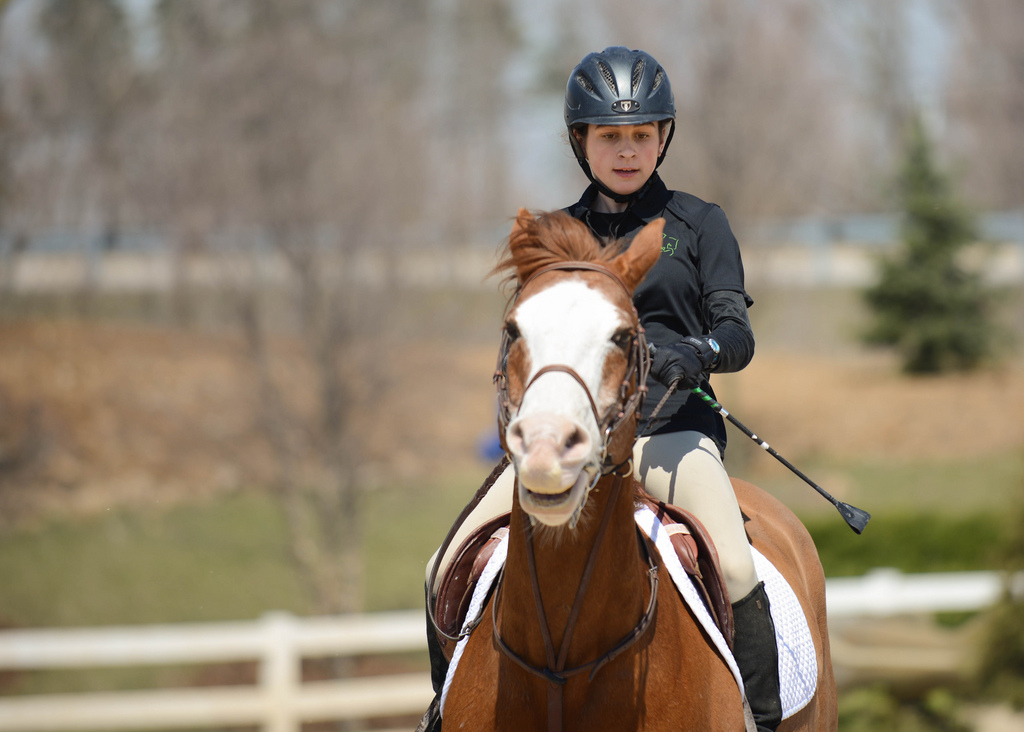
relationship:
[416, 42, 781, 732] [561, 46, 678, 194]
girl wearing helmet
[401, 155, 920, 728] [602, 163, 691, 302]
horse has ear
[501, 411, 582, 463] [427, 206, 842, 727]
nose of horse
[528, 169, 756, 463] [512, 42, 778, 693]
jacket on girl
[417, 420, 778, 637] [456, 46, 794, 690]
pants on girl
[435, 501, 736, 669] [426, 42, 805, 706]
saddle under girl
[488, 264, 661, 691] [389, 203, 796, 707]
bridle on horse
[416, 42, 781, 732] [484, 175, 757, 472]
girl in a jacket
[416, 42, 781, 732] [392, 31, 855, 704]
girl riding a horse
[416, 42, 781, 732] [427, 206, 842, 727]
girl riding a horse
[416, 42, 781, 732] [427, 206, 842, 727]
girl sitting on a horse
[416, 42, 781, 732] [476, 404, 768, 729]
girl wearing pants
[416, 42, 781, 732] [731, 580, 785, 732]
girl wearing boots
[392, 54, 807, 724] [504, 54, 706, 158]
girl wearing helmet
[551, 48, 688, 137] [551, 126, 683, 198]
helmet has strap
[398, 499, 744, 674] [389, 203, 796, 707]
saddle on horse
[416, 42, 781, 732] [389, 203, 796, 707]
girl riding horse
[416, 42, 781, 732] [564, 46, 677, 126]
girl in helmet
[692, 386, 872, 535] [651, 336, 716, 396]
pole held in hand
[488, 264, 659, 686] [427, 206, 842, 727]
bridle controlling horse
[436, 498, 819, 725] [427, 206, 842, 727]
blanket on horse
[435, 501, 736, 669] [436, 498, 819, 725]
saddle on blanket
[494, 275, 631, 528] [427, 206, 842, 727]
face on horse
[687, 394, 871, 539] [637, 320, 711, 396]
pole on hand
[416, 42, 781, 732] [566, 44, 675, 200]
girl wearing helmet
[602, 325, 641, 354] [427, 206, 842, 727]
eye on horse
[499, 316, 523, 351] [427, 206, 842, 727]
eye on horse